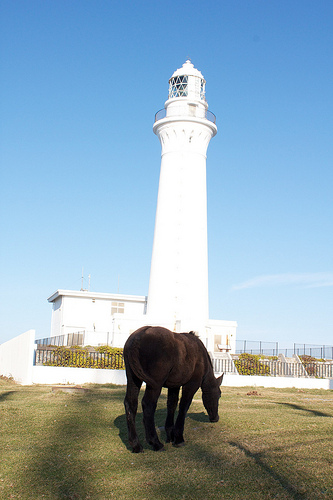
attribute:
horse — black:
[123, 325, 222, 452]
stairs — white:
[211, 349, 238, 373]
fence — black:
[231, 338, 332, 358]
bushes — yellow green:
[43, 344, 125, 370]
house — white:
[47, 288, 236, 350]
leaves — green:
[231, 352, 269, 377]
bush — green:
[234, 352, 269, 375]